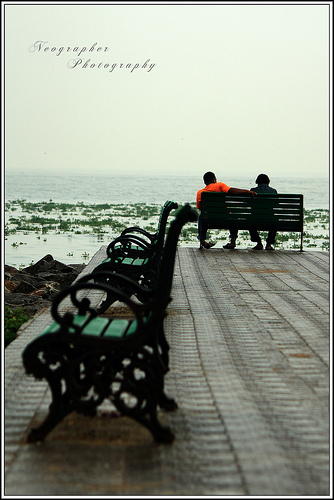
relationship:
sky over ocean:
[9, 8, 329, 161] [6, 165, 321, 219]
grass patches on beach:
[8, 203, 145, 230] [15, 198, 327, 255]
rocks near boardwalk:
[9, 254, 70, 344] [2, 247, 327, 496]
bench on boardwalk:
[199, 190, 300, 250] [2, 247, 327, 496]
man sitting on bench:
[196, 171, 257, 250] [199, 190, 300, 250]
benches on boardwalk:
[34, 197, 190, 446] [2, 247, 327, 496]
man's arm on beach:
[225, 183, 247, 193] [15, 198, 327, 255]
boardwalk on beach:
[2, 247, 327, 496] [15, 198, 327, 255]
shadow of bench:
[39, 410, 197, 499] [20, 289, 177, 447]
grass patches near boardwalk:
[8, 203, 145, 230] [2, 247, 327, 496]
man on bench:
[196, 171, 257, 250] [199, 190, 300, 250]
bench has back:
[199, 190, 300, 250] [201, 196, 302, 226]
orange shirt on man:
[197, 184, 226, 200] [198, 176, 248, 241]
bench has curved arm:
[20, 289, 177, 447] [53, 285, 145, 335]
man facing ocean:
[196, 171, 257, 250] [6, 165, 321, 219]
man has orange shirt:
[198, 176, 248, 241] [197, 184, 226, 200]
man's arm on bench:
[225, 183, 247, 193] [199, 190, 300, 250]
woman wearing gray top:
[250, 173, 283, 251] [249, 186, 278, 203]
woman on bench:
[250, 173, 283, 251] [199, 190, 300, 250]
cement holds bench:
[24, 398, 169, 453] [20, 289, 177, 447]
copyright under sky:
[34, 36, 159, 76] [9, 8, 329, 161]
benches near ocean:
[34, 197, 190, 446] [6, 165, 321, 219]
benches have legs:
[34, 197, 190, 446] [38, 384, 184, 454]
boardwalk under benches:
[2, 247, 327, 496] [34, 197, 190, 446]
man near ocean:
[196, 171, 257, 250] [6, 165, 321, 219]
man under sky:
[196, 171, 257, 250] [9, 8, 329, 161]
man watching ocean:
[196, 171, 257, 250] [6, 165, 321, 219]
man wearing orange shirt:
[198, 176, 248, 241] [197, 184, 226, 200]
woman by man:
[250, 173, 283, 251] [198, 176, 248, 241]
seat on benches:
[43, 311, 136, 348] [34, 197, 190, 446]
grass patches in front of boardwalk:
[8, 203, 145, 230] [2, 247, 327, 496]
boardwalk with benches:
[2, 247, 327, 496] [34, 197, 190, 446]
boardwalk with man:
[2, 247, 327, 496] [196, 171, 257, 250]